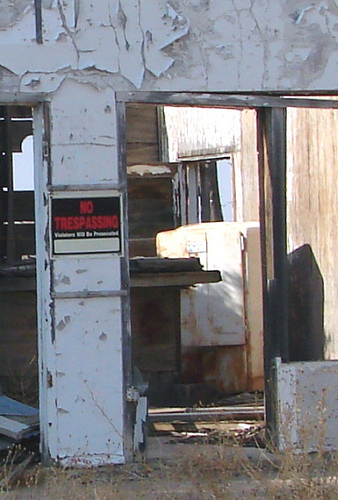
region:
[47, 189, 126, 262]
Black, white, and red sign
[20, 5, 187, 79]
White peeling paint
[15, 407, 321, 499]
Light brown plants in the foreground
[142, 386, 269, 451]
Wooden boards on the ground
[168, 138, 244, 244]
Window in the back of the building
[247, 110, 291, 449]
Tall wooden plank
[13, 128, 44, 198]
Window in the back of the building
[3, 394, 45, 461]
Scraps of wood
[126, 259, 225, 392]
Wooden counter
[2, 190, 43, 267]
Wooden planks underneath window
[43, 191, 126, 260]
white sign with red writing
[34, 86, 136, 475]
part of a house with peeling paint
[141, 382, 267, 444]
some rubble lying on the ground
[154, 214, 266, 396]
an old rusty refrigerator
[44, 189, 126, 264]
a sign on a wall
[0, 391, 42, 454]
some rubble lying on the ground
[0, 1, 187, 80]
part of a wall with peeling paint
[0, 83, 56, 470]
a doorway without a door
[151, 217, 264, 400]
old white fridge covered in rust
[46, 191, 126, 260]
a no trespassing sign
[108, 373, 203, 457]
the wall is broken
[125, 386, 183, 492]
the wall is broken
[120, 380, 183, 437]
the wall is broken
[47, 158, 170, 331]
a sign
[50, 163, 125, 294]
a sign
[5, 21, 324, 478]
A dilapidated building is pictured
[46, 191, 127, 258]
This is a No Trespassing sign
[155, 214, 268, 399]
An old refrigerator is inside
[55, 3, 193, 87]
The paint on the building is cracking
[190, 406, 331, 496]
Weeds are growing here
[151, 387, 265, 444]
Debris is lying on the floor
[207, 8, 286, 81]
Cracks are in the wall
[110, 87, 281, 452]
This is a door frame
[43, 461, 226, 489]
The ground is seen here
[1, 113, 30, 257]
The interior wall is made of wooden boards